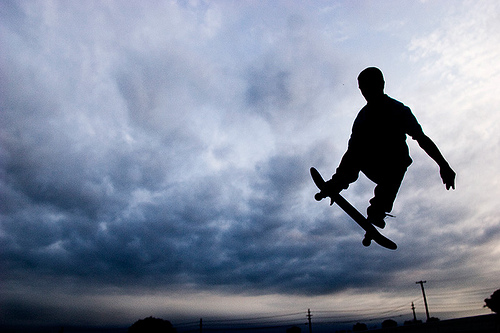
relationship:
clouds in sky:
[2, 2, 498, 294] [2, 1, 499, 321]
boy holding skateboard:
[324, 66, 456, 228] [309, 167, 397, 252]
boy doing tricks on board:
[324, 66, 456, 228] [308, 167, 397, 250]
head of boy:
[357, 66, 385, 103] [324, 66, 456, 228]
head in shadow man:
[358, 65, 385, 103] [325, 67, 460, 226]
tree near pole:
[483, 282, 499, 320] [414, 279, 436, 317]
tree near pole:
[483, 282, 499, 320] [409, 301, 419, 314]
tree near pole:
[483, 282, 499, 320] [302, 305, 315, 326]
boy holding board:
[324, 66, 456, 228] [317, 165, 392, 245]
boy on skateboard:
[324, 66, 456, 228] [266, 149, 418, 286]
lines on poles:
[200, 280, 499, 328] [388, 258, 443, 331]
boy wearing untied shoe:
[324, 66, 456, 228] [366, 202, 396, 229]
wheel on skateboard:
[306, 179, 325, 205] [301, 162, 407, 257]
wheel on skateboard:
[356, 224, 376, 253] [301, 162, 407, 257]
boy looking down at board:
[324, 66, 456, 228] [300, 161, 402, 261]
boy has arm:
[311, 65, 454, 227] [405, 106, 460, 194]